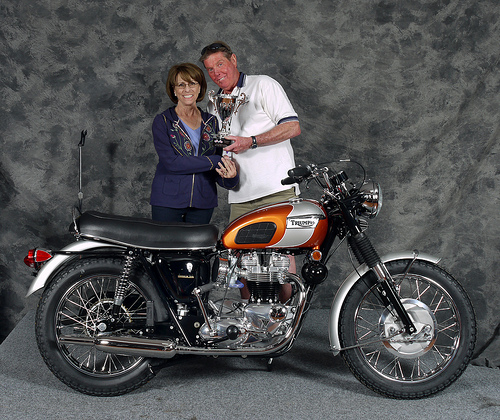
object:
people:
[149, 40, 300, 358]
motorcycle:
[24, 158, 478, 402]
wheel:
[35, 253, 172, 398]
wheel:
[336, 258, 476, 401]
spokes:
[56, 276, 146, 374]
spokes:
[356, 277, 456, 382]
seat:
[68, 210, 221, 250]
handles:
[281, 164, 308, 196]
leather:
[125, 227, 188, 239]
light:
[357, 179, 383, 220]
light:
[24, 249, 53, 271]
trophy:
[207, 89, 249, 148]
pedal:
[191, 283, 213, 337]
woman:
[147, 62, 239, 351]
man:
[198, 40, 303, 355]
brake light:
[24, 248, 35, 268]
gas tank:
[222, 198, 328, 251]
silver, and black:
[81, 242, 96, 247]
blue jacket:
[150, 105, 241, 209]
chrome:
[406, 305, 432, 325]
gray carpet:
[0, 308, 500, 420]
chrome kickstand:
[267, 356, 275, 372]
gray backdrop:
[0, 0, 500, 371]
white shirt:
[206, 71, 300, 204]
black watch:
[251, 136, 258, 149]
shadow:
[0, 326, 385, 397]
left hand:
[223, 135, 249, 155]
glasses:
[172, 79, 200, 89]